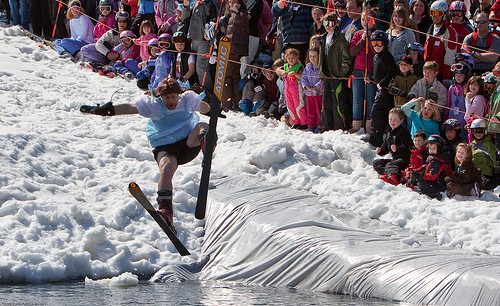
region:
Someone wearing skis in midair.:
[79, 35, 231, 255]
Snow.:
[0, 26, 499, 286]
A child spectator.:
[443, 141, 481, 198]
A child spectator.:
[372, 107, 416, 183]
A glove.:
[79, 86, 123, 116]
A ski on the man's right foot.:
[127, 181, 191, 256]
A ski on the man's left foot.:
[193, 36, 231, 219]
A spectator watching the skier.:
[422, 1, 459, 88]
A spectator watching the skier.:
[52, 0, 93, 60]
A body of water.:
[0, 274, 420, 304]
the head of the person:
[149, 73, 186, 115]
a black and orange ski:
[121, 176, 198, 261]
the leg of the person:
[153, 143, 185, 233]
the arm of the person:
[77, 93, 153, 125]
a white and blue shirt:
[137, 85, 212, 150]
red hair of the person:
[149, 74, 191, 97]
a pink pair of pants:
[282, 65, 304, 127]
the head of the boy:
[384, 103, 413, 130]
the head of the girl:
[410, 97, 442, 122]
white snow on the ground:
[0, 17, 499, 304]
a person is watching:
[275, 45, 302, 127]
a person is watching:
[296, 45, 331, 132]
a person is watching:
[238, 55, 263, 113]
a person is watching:
[265, 68, 282, 115]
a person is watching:
[380, 109, 412, 182]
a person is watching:
[405, 127, 436, 191]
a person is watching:
[417, 135, 452, 195]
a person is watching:
[447, 140, 479, 196]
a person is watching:
[403, 53, 445, 108]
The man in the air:
[78, 29, 233, 266]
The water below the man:
[0, 271, 409, 304]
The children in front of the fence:
[371, 98, 499, 201]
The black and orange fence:
[50, 1, 497, 130]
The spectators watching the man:
[1, 0, 498, 202]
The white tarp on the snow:
[156, 176, 498, 305]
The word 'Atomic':
[213, 43, 233, 97]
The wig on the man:
[143, 78, 186, 97]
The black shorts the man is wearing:
[151, 134, 203, 170]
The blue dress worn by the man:
[133, 95, 202, 143]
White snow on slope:
[8, 101, 86, 246]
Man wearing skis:
[111, 48, 252, 285]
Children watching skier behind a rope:
[279, 43, 330, 124]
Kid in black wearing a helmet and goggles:
[366, 26, 394, 128]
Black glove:
[76, 93, 121, 130]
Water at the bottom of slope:
[13, 238, 203, 304]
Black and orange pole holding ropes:
[353, 8, 377, 140]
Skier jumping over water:
[83, 37, 245, 266]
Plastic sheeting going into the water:
[220, 160, 341, 300]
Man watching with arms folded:
[461, 8, 498, 65]